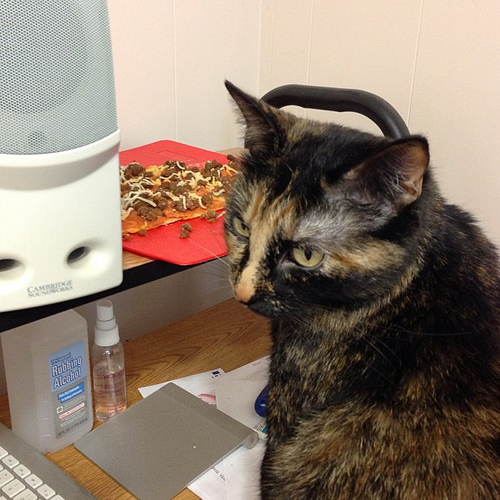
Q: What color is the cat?
A: Black and brown.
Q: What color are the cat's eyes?
A: Green.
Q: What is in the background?
A: Pizza.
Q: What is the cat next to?
A: A speaker.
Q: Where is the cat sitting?
A: On desk.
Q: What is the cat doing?
A: Staring.